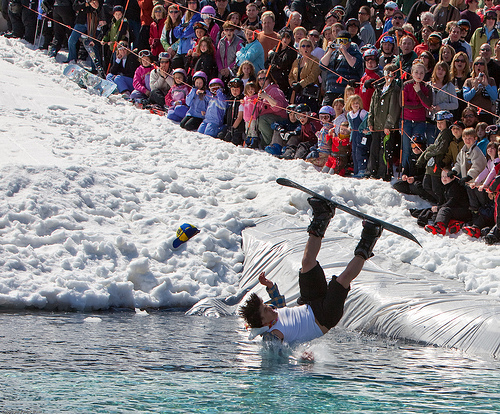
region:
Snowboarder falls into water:
[237, 175, 417, 361]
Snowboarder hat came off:
[172, 170, 422, 361]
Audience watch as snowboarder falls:
[96, 0, 496, 358]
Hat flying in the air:
[170, 222, 201, 250]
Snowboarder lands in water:
[239, 175, 421, 365]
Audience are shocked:
[163, 1, 498, 177]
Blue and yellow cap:
[168, 219, 207, 248]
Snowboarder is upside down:
[239, 176, 426, 365]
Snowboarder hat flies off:
[170, 176, 423, 365]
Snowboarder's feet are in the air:
[239, 178, 422, 363]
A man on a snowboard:
[236, 170, 428, 353]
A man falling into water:
[228, 173, 429, 393]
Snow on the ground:
[2, 75, 232, 307]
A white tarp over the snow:
[230, 210, 495, 360]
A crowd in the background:
[6, 3, 496, 250]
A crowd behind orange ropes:
[98, 1, 488, 166]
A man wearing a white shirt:
[242, 290, 326, 350]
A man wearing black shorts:
[293, 256, 353, 331]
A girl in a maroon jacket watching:
[398, 55, 435, 126]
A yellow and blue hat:
[171, 222, 201, 251]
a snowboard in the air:
[280, 169, 417, 251]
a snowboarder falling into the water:
[230, 174, 427, 363]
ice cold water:
[3, 290, 498, 410]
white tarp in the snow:
[251, 212, 498, 372]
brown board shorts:
[289, 251, 356, 338]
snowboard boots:
[300, 191, 382, 263]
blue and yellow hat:
[174, 215, 203, 252]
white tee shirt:
[254, 288, 323, 349]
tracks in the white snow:
[4, 48, 492, 340]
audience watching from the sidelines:
[1, 1, 498, 237]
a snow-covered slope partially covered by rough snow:
[0, 34, 271, 306]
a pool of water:
[1, 308, 495, 411]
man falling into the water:
[238, 196, 381, 368]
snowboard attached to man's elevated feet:
[275, 173, 421, 249]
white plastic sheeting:
[188, 214, 499, 356]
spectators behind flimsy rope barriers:
[3, 1, 495, 243]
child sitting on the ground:
[422, 166, 465, 238]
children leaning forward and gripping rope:
[422, 108, 499, 201]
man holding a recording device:
[317, 28, 363, 86]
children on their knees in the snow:
[163, 68, 246, 145]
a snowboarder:
[215, 164, 425, 371]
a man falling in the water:
[231, 170, 422, 367]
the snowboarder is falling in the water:
[229, 170, 401, 370]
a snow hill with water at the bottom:
[3, 37, 494, 347]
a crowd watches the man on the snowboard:
[6, 0, 498, 222]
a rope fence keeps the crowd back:
[39, 2, 489, 187]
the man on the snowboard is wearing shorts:
[238, 161, 435, 371]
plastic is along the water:
[238, 209, 498, 364]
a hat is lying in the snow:
[164, 215, 211, 254]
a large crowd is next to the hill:
[11, 1, 495, 242]